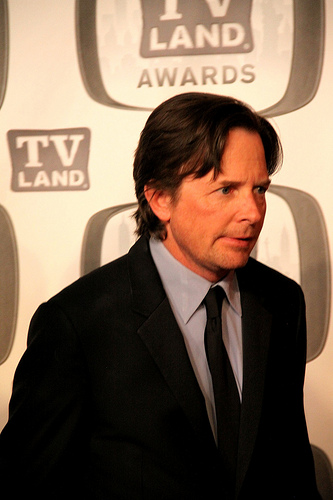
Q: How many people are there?
A: One.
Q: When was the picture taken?
A: During awards.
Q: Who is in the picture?
A: Michael J Fox.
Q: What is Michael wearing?
A: A suit.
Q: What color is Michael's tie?
A: Black.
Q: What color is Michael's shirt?
A: Grey.